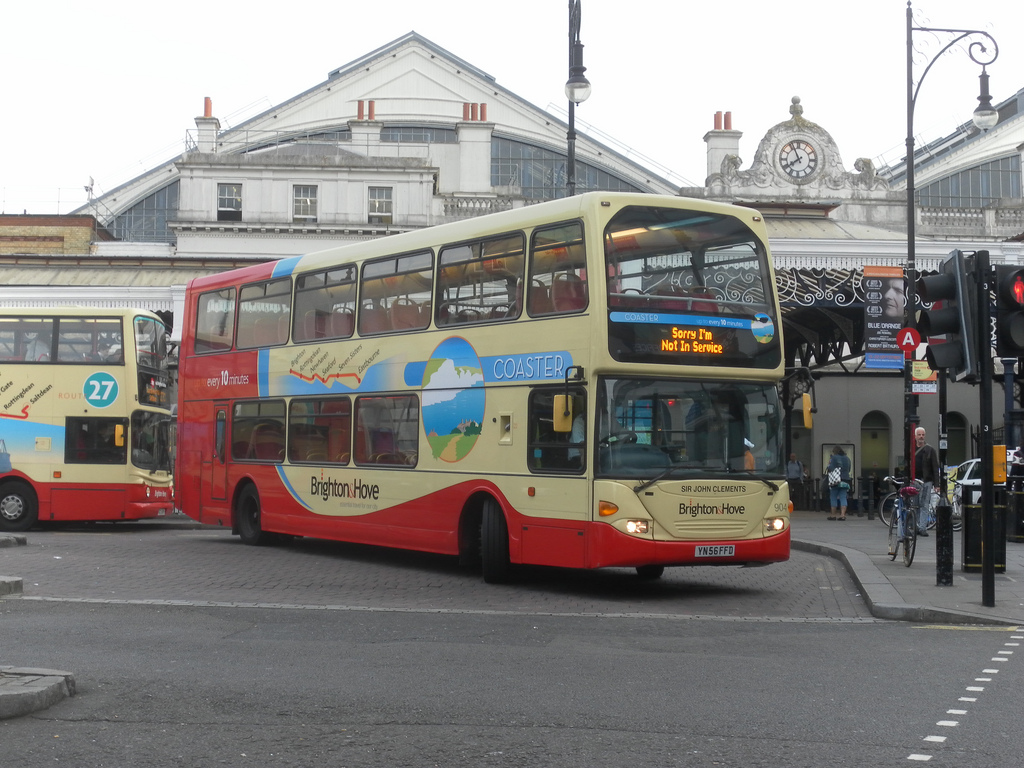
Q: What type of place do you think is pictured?
A: It is a roadway.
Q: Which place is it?
A: It is a roadway.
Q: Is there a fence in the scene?
A: No, there are no fences.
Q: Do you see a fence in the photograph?
A: No, there are no fences.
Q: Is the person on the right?
A: Yes, the person is on the right of the image.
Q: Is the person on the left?
A: No, the person is on the right of the image.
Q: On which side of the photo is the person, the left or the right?
A: The person is on the right of the image.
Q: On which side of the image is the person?
A: The person is on the right of the image.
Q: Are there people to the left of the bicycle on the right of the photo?
A: Yes, there is a person to the left of the bicycle.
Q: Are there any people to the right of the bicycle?
A: No, the person is to the left of the bicycle.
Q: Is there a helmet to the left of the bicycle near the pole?
A: No, there is a person to the left of the bicycle.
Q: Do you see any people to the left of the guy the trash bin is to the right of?
A: Yes, there is a person to the left of the guy.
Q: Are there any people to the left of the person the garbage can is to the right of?
A: Yes, there is a person to the left of the guy.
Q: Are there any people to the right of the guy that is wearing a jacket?
A: No, the person is to the left of the guy.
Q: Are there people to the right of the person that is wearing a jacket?
A: No, the person is to the left of the guy.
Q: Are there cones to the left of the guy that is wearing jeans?
A: No, there is a person to the left of the guy.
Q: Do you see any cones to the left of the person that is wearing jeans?
A: No, there is a person to the left of the guy.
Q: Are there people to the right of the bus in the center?
A: Yes, there is a person to the right of the bus.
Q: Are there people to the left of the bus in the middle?
A: No, the person is to the right of the bus.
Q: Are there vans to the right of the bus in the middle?
A: No, there is a person to the right of the bus.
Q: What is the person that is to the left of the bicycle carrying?
A: The person is carrying a bag.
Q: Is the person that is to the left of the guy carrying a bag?
A: Yes, the person is carrying a bag.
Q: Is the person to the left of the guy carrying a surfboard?
A: No, the person is carrying a bag.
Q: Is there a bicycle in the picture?
A: Yes, there is a bicycle.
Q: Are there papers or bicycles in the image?
A: Yes, there is a bicycle.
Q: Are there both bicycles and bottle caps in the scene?
A: No, there is a bicycle but no bottle caps.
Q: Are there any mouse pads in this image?
A: No, there are no mouse pads.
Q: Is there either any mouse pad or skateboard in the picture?
A: No, there are no mouse pads or skateboards.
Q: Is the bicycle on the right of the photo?
A: Yes, the bicycle is on the right of the image.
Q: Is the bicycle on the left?
A: No, the bicycle is on the right of the image.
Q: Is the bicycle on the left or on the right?
A: The bicycle is on the right of the image.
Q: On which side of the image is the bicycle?
A: The bicycle is on the right of the image.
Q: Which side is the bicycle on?
A: The bicycle is on the right of the image.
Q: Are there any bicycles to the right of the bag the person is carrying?
A: Yes, there is a bicycle to the right of the bag.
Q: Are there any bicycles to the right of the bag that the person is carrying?
A: Yes, there is a bicycle to the right of the bag.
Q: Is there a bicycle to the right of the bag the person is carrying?
A: Yes, there is a bicycle to the right of the bag.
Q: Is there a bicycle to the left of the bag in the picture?
A: No, the bicycle is to the right of the bag.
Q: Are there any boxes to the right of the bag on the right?
A: No, there is a bicycle to the right of the bag.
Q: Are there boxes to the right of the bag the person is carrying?
A: No, there is a bicycle to the right of the bag.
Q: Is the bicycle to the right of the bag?
A: Yes, the bicycle is to the right of the bag.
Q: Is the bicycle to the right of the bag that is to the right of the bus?
A: Yes, the bicycle is to the right of the bag.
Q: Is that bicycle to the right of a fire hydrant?
A: No, the bicycle is to the right of the bag.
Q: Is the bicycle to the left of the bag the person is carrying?
A: No, the bicycle is to the right of the bag.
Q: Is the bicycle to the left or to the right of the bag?
A: The bicycle is to the right of the bag.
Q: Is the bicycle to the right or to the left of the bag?
A: The bicycle is to the right of the bag.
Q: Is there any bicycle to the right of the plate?
A: Yes, there is a bicycle to the right of the plate.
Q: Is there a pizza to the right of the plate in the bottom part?
A: No, there is a bicycle to the right of the plate.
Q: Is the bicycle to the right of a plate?
A: Yes, the bicycle is to the right of a plate.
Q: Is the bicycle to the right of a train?
A: No, the bicycle is to the right of a plate.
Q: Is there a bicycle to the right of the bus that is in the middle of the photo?
A: Yes, there is a bicycle to the right of the bus.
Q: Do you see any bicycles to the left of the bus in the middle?
A: No, the bicycle is to the right of the bus.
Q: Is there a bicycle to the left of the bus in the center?
A: No, the bicycle is to the right of the bus.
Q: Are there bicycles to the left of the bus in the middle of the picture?
A: No, the bicycle is to the right of the bus.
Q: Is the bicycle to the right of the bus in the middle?
A: Yes, the bicycle is to the right of the bus.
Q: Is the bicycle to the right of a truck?
A: No, the bicycle is to the right of the bus.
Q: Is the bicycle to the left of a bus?
A: No, the bicycle is to the right of a bus.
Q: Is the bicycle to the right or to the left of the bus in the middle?
A: The bicycle is to the right of the bus.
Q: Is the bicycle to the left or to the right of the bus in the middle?
A: The bicycle is to the right of the bus.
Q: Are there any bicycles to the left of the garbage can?
A: Yes, there is a bicycle to the left of the garbage can.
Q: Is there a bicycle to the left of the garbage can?
A: Yes, there is a bicycle to the left of the garbage can.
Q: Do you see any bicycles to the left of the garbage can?
A: Yes, there is a bicycle to the left of the garbage can.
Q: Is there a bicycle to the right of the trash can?
A: No, the bicycle is to the left of the trash can.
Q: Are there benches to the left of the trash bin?
A: No, there is a bicycle to the left of the trash bin.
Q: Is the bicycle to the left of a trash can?
A: Yes, the bicycle is to the left of a trash can.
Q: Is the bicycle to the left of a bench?
A: No, the bicycle is to the left of a trash can.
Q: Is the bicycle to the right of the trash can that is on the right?
A: No, the bicycle is to the left of the garbage bin.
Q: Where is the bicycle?
A: The bicycle is on the sidewalk.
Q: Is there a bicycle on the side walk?
A: Yes, there is a bicycle on the side walk.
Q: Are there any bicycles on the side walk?
A: Yes, there is a bicycle on the side walk.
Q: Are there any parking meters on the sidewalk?
A: No, there is a bicycle on the sidewalk.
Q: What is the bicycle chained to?
A: The bicycle is chained to the pole.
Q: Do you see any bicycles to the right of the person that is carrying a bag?
A: Yes, there is a bicycle to the right of the person.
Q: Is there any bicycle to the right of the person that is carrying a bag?
A: Yes, there is a bicycle to the right of the person.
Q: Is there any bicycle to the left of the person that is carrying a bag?
A: No, the bicycle is to the right of the person.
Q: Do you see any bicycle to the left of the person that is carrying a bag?
A: No, the bicycle is to the right of the person.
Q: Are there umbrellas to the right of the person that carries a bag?
A: No, there is a bicycle to the right of the person.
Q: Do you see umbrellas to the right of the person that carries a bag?
A: No, there is a bicycle to the right of the person.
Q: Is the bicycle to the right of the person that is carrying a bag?
A: Yes, the bicycle is to the right of the person.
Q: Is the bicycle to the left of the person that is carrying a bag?
A: No, the bicycle is to the right of the person.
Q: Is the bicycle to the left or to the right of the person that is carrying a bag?
A: The bicycle is to the right of the person.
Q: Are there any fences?
A: No, there are no fences.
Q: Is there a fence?
A: No, there are no fences.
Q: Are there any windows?
A: Yes, there is a window.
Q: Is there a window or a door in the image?
A: Yes, there is a window.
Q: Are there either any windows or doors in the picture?
A: Yes, there is a window.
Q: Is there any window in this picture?
A: Yes, there is a window.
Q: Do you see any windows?
A: Yes, there is a window.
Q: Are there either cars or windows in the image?
A: Yes, there is a window.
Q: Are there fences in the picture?
A: No, there are no fences.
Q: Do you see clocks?
A: Yes, there is a clock.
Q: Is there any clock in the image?
A: Yes, there is a clock.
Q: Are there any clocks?
A: Yes, there is a clock.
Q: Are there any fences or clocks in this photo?
A: Yes, there is a clock.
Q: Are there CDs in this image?
A: No, there are no cds.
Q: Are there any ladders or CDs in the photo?
A: No, there are no CDs or ladders.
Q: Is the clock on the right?
A: Yes, the clock is on the right of the image.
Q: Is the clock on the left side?
A: No, the clock is on the right of the image.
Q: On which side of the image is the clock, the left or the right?
A: The clock is on the right of the image.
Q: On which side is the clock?
A: The clock is on the right of the image.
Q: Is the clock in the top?
A: Yes, the clock is in the top of the image.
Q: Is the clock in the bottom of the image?
A: No, the clock is in the top of the image.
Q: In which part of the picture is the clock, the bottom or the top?
A: The clock is in the top of the image.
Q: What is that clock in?
A: The clock is in the tower.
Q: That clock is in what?
A: The clock is in the tower.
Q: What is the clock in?
A: The clock is in the tower.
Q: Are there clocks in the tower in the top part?
A: Yes, there is a clock in the tower.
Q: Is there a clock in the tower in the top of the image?
A: Yes, there is a clock in the tower.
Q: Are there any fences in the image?
A: No, there are no fences.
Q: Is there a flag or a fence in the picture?
A: No, there are no fences or flags.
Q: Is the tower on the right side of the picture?
A: Yes, the tower is on the right of the image.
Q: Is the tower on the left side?
A: No, the tower is on the right of the image.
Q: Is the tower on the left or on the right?
A: The tower is on the right of the image.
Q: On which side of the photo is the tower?
A: The tower is on the right of the image.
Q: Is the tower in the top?
A: Yes, the tower is in the top of the image.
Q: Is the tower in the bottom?
A: No, the tower is in the top of the image.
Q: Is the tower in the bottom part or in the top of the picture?
A: The tower is in the top of the image.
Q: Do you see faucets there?
A: No, there are no faucets.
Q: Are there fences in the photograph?
A: No, there are no fences.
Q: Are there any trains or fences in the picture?
A: No, there are no fences or trains.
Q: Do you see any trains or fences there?
A: No, there are no fences or trains.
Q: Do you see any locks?
A: No, there are no locks.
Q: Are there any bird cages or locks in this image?
A: No, there are no locks or bird cages.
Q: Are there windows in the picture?
A: Yes, there is a window.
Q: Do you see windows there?
A: Yes, there is a window.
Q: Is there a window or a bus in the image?
A: Yes, there is a window.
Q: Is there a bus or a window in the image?
A: Yes, there is a window.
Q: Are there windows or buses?
A: Yes, there is a window.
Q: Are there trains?
A: No, there are no trains.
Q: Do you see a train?
A: No, there are no trains.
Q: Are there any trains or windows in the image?
A: Yes, there is a window.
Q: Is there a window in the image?
A: Yes, there is a window.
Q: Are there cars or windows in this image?
A: Yes, there is a window.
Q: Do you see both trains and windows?
A: No, there is a window but no trains.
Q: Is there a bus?
A: Yes, there is a bus.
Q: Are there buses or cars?
A: Yes, there is a bus.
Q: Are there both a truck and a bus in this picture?
A: No, there is a bus but no trucks.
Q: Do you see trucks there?
A: No, there are no trucks.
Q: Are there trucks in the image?
A: No, there are no trucks.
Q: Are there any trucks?
A: No, there are no trucks.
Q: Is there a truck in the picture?
A: No, there are no trucks.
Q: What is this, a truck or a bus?
A: This is a bus.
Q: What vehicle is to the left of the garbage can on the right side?
A: The vehicle is a bus.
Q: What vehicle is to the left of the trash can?
A: The vehicle is a bus.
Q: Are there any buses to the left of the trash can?
A: Yes, there is a bus to the left of the trash can.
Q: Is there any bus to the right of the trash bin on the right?
A: No, the bus is to the left of the garbage can.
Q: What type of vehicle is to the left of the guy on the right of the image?
A: The vehicle is a bus.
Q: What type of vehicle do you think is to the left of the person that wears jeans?
A: The vehicle is a bus.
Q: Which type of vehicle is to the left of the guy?
A: The vehicle is a bus.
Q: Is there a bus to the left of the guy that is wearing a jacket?
A: Yes, there is a bus to the left of the guy.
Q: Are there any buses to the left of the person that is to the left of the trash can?
A: Yes, there is a bus to the left of the guy.